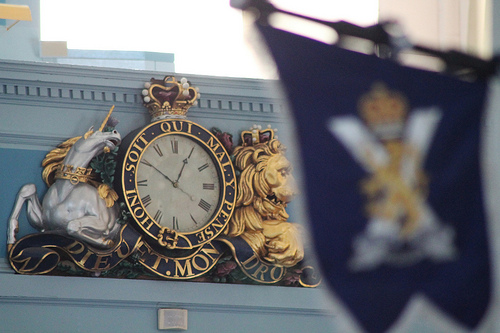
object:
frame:
[114, 123, 237, 236]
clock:
[118, 116, 242, 247]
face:
[134, 133, 224, 234]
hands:
[146, 154, 196, 202]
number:
[139, 165, 154, 226]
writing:
[123, 133, 150, 194]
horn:
[93, 101, 120, 135]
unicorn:
[56, 127, 123, 186]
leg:
[6, 184, 44, 250]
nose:
[109, 128, 126, 137]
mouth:
[102, 134, 123, 147]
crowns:
[139, 71, 203, 122]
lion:
[235, 146, 299, 227]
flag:
[325, 80, 463, 272]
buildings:
[2, 31, 262, 151]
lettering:
[120, 117, 240, 238]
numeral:
[147, 135, 184, 159]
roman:
[126, 113, 179, 163]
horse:
[7, 129, 129, 255]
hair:
[42, 133, 84, 186]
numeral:
[184, 144, 196, 158]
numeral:
[198, 160, 212, 171]